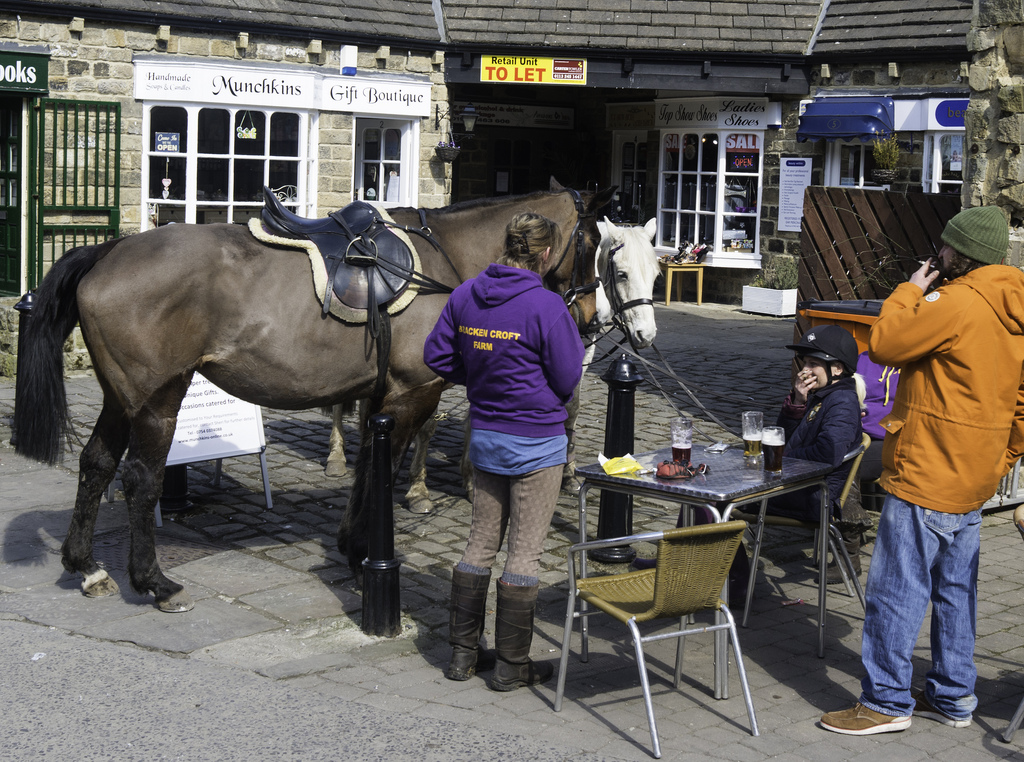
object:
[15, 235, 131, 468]
tail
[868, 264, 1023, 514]
jacket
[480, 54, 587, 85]
sign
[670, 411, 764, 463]
glasses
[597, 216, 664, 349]
head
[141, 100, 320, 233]
window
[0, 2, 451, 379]
building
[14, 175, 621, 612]
horse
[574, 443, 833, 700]
table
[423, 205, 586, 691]
female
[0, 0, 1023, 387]
building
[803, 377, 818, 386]
mouth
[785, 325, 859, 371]
hat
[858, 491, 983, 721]
blue jeans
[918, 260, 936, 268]
cigarette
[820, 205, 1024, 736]
man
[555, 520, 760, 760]
chair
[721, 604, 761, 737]
leg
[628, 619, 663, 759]
leg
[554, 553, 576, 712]
leg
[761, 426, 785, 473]
drink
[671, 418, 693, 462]
drink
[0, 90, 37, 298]
door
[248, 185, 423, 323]
saddle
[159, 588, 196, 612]
hoof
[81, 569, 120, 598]
hoof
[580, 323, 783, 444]
reins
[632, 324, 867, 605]
girl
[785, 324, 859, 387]
helmet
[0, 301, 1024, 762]
square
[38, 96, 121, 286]
doorway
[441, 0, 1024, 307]
shop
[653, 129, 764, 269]
window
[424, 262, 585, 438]
sweatshirt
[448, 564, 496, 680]
boot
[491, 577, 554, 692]
boot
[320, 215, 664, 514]
horse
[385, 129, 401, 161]
glass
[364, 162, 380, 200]
glass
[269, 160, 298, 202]
glass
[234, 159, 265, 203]
glass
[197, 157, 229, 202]
glass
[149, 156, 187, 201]
glass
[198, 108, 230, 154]
glass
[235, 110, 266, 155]
glass